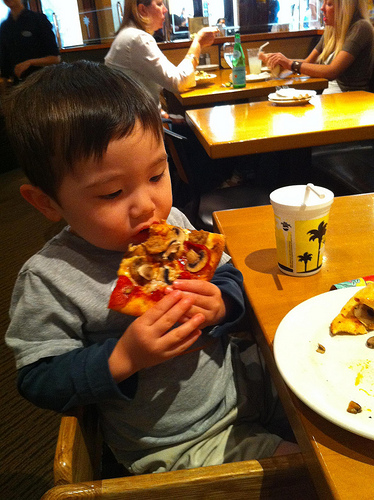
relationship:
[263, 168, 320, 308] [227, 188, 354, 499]
cup on table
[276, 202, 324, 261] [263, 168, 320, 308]
palm tree on cup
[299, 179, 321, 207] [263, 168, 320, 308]
straw in cup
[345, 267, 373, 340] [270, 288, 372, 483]
food on plate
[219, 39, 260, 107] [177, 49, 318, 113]
bottle on table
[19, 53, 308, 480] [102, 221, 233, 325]
boy holds pizza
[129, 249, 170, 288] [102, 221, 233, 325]
mushrooms on pizza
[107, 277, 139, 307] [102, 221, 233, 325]
pepperoni on pizza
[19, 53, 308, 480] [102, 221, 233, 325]
boy eats pizza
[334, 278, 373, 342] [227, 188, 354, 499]
pizza on table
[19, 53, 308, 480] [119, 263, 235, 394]
boy has hands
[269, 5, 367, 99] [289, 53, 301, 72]
woman has bracelets